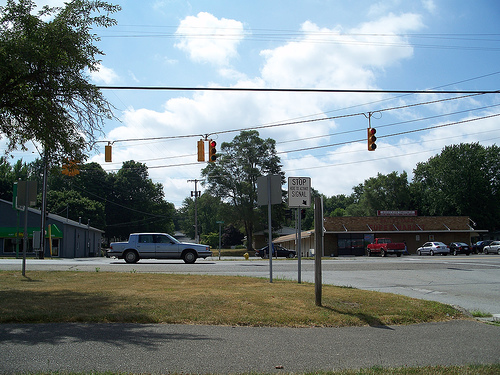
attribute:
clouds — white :
[83, 12, 445, 185]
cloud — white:
[170, 10, 242, 72]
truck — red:
[365, 240, 405, 258]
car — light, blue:
[84, 232, 244, 289]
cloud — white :
[173, 12, 248, 65]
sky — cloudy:
[110, 9, 477, 140]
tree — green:
[0, 1, 127, 177]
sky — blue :
[97, 17, 178, 82]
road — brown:
[266, 257, 371, 271]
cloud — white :
[166, 11, 251, 65]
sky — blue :
[119, 42, 172, 74]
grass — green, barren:
[1, 266, 479, 326]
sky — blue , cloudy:
[2, 4, 498, 215]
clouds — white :
[302, 120, 499, 186]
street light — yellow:
[365, 127, 376, 153]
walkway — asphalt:
[7, 316, 498, 368]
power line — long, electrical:
[102, 22, 499, 41]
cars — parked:
[151, 166, 498, 292]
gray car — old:
[106, 231, 213, 263]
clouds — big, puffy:
[174, 11, 422, 140]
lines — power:
[0, 7, 495, 172]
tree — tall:
[106, 162, 166, 235]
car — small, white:
[105, 232, 212, 263]